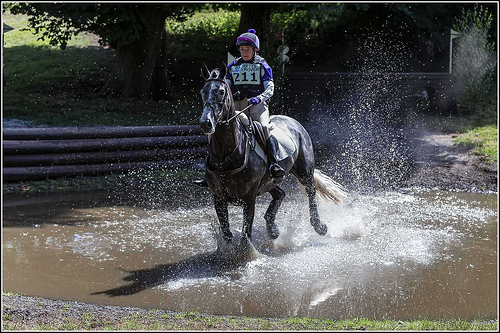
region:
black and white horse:
[199, 71, 329, 239]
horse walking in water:
[199, 70, 329, 249]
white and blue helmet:
[241, 33, 260, 50]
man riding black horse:
[230, 28, 275, 173]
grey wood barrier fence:
[3, 126, 206, 193]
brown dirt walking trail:
[405, 112, 490, 197]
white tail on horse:
[316, 171, 347, 205]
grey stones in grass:
[6, 293, 232, 330]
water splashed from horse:
[336, 96, 401, 196]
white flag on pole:
[448, 28, 455, 68]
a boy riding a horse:
[87, 15, 365, 262]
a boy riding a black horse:
[161, 15, 408, 277]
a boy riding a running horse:
[152, 4, 380, 287]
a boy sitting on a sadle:
[140, 15, 308, 208]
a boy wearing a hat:
[162, 19, 325, 204]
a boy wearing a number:
[192, 5, 325, 175]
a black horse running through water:
[141, 21, 366, 285]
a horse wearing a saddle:
[133, 15, 413, 282]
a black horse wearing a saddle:
[143, 22, 375, 251]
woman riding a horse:
[201, 30, 344, 247]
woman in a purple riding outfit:
[225, 27, 281, 176]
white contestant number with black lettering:
[232, 62, 258, 82]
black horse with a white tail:
[199, 65, 344, 252]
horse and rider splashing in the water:
[197, 20, 462, 266]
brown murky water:
[2, 190, 490, 320]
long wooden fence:
[2, 125, 208, 177]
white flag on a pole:
[450, 27, 460, 69]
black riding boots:
[267, 136, 282, 180]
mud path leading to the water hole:
[323, 113, 496, 195]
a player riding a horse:
[163, 18, 353, 274]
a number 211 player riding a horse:
[152, 8, 364, 269]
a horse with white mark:
[190, 73, 274, 266]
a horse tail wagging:
[320, 165, 350, 210]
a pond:
[385, 218, 452, 288]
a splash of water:
[332, 204, 369, 264]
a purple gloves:
[246, 92, 260, 107]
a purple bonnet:
[233, 25, 268, 50]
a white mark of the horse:
[197, 71, 220, 115]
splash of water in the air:
[340, 79, 366, 118]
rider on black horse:
[200, 32, 355, 252]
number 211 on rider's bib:
[232, 71, 260, 88]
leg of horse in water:
[257, 193, 287, 245]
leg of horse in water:
[294, 184, 328, 244]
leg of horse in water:
[236, 207, 251, 266]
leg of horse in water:
[206, 195, 231, 252]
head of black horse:
[193, 72, 235, 139]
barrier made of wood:
[33, 118, 84, 183]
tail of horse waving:
[305, 177, 340, 202]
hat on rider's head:
[236, 30, 258, 47]